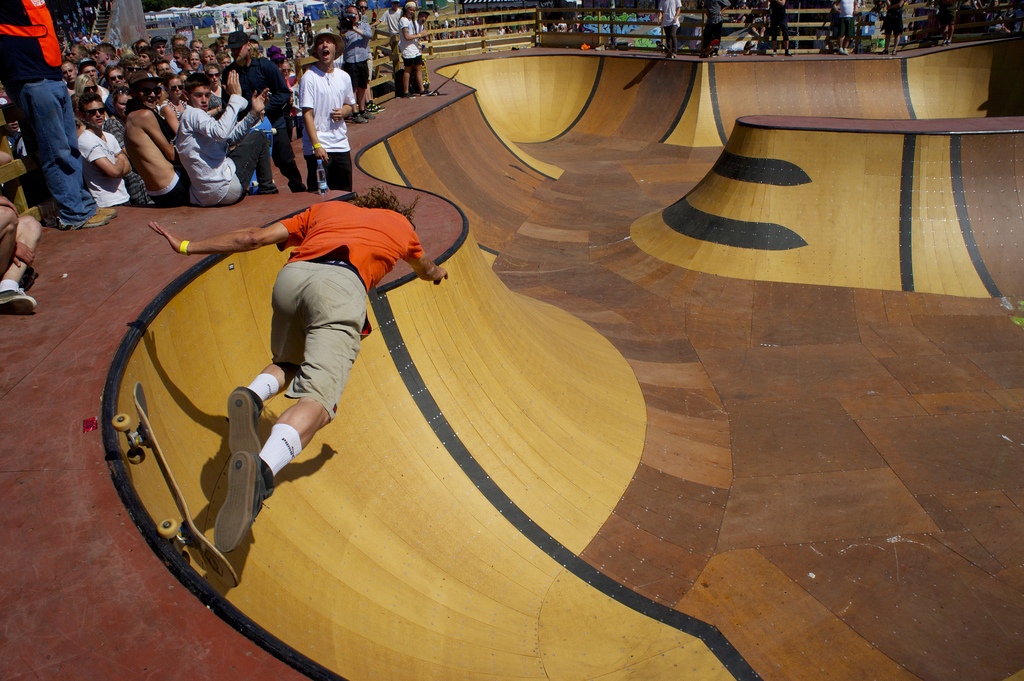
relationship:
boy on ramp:
[124, 155, 472, 575] [34, 29, 1023, 673]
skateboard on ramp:
[108, 371, 239, 590] [34, 29, 1023, 673]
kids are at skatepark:
[33, 6, 394, 210] [6, 8, 1024, 666]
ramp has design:
[34, 29, 1023, 673] [641, 142, 834, 273]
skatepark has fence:
[6, 8, 1024, 666] [287, 3, 939, 67]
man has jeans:
[6, 0, 129, 238] [12, 67, 106, 230]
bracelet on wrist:
[175, 238, 194, 252] [169, 227, 204, 269]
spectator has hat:
[122, 61, 195, 211] [135, 62, 169, 91]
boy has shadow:
[124, 155, 472, 575] [130, 308, 344, 612]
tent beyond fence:
[164, 0, 311, 42] [287, 3, 939, 67]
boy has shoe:
[124, 155, 472, 575] [208, 388, 275, 461]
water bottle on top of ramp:
[308, 142, 335, 204] [34, 29, 1023, 673]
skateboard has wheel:
[108, 371, 239, 590] [109, 403, 135, 438]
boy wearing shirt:
[124, 155, 472, 575] [280, 195, 446, 307]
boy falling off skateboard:
[124, 155, 472, 575] [108, 371, 239, 590]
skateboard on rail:
[108, 371, 239, 590] [105, 201, 362, 679]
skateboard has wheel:
[108, 371, 239, 590] [156, 507, 185, 542]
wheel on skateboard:
[132, 441, 153, 471] [108, 371, 239, 590]